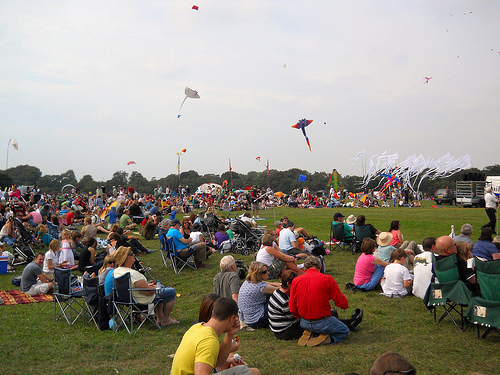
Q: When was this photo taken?
A: Daytime.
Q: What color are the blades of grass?
A: Green.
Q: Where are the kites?
A: In the sky.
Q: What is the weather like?
A: Cloudy.